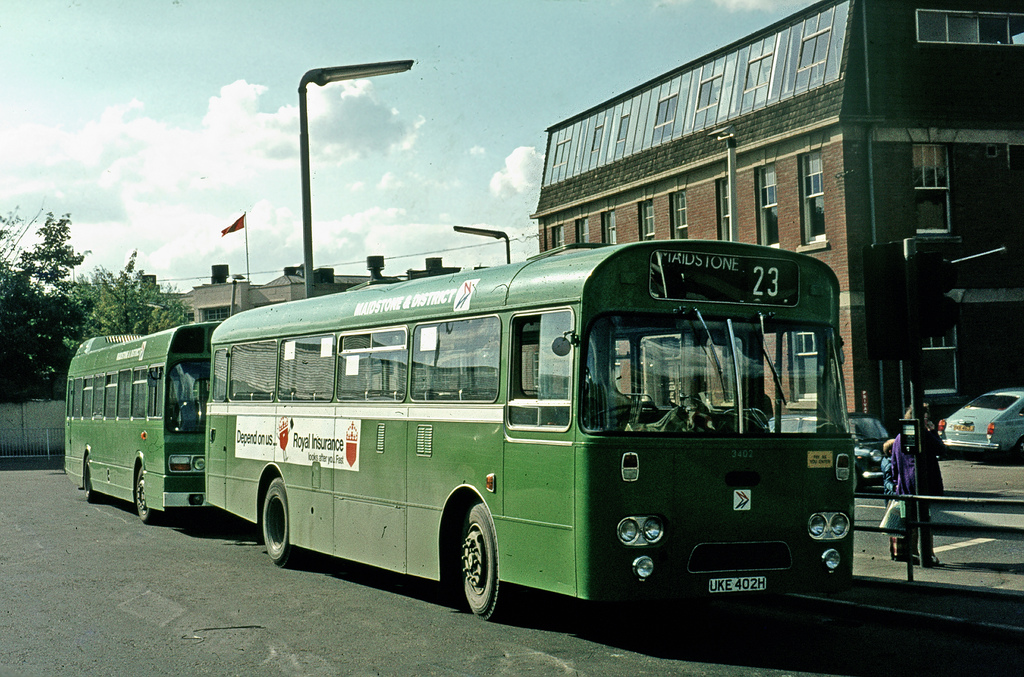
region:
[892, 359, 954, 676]
a person standing at the stop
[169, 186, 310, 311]
A flag waving in the breeze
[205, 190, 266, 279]
a red flag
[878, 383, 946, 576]
a woman and child waiting on the street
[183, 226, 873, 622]
a green city bus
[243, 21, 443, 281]
a streetlight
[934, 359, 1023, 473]
a blue car parked on the street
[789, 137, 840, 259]
a window on a building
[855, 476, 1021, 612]
a metal fence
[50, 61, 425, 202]
clouds in the sky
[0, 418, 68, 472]
a metal barricade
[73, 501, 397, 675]
Grey road with evidence of heaves and cracks.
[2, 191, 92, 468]
White fence and high green trees, left, in distance.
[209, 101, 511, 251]
Flag, streetlight and utility pole.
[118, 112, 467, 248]
Pale blue sky with light clouds.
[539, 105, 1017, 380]
Red brick building.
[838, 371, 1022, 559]
Parking lot with cars.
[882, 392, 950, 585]
Two people, one with bag and purple garment.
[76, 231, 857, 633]
Two flat-faced buses, shown nose-to-tail.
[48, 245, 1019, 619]
Passenger buses, alongside rail, are green.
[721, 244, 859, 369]
One shows number 23.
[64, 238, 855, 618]
Two green parked buses.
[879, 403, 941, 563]
two people standing on the sidewalk.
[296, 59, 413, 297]
A large black street lamp.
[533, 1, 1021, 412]
A brick building.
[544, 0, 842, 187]
A row of black windows.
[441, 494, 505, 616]
The front tire on a bus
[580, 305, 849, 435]
An old bus's front windshield.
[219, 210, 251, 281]
A flag on a tall flag pole flapping in the breeze.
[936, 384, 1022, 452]
A parked blue car.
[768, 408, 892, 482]
A black car driving in the street.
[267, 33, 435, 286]
Tall metal street light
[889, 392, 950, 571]
Adult person wearing a purple jacket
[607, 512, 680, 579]
Headlights on a large bus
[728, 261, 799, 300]
Number "23" indicating the bus route.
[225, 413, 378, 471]
Insurance advertisement sign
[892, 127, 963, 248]
Tall window on large building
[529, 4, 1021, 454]
Large brick building in the background.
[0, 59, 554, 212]
Puffy white clouds in the sky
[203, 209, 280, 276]
Flag flying on a flag pole.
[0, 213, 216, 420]
Green leafy trees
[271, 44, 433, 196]
Street lamp with cloudy background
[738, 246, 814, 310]
Number 23 on front of bus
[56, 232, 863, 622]
Two parked green buses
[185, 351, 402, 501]
Advertising on side of bus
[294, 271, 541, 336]
Advertising on top of bus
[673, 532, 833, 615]
License plate on first bus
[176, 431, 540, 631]
Very dusty bus tires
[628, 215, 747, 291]
Destination displayed on first bus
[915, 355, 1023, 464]
Car parked next to building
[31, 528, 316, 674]
Surface on which buses are parked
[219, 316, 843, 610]
the bus is green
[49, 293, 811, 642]
there are two buses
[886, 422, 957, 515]
the jacket is purple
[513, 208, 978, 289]
the building is brown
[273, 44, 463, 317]
the lamp post is beside the bus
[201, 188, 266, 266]
the flag is on the building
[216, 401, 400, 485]
the paint is white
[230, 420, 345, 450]
the texts are black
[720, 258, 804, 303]
the bus number is 23